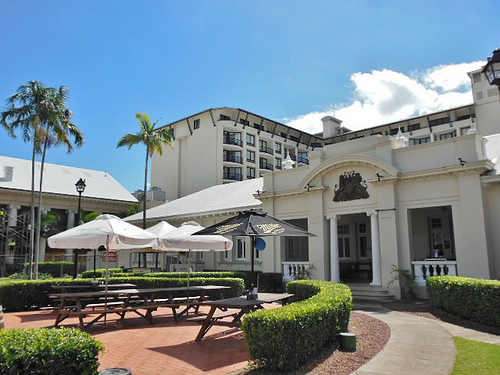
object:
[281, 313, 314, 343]
leaves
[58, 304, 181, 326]
bench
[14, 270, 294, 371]
shade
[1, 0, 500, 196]
sky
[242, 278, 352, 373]
hedge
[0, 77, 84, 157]
palms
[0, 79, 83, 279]
palm tree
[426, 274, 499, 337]
hedge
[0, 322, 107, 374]
hedge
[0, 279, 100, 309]
hedge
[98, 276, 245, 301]
hedge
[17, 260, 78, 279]
hedge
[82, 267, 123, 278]
hedge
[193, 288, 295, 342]
table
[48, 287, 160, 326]
table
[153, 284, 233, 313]
table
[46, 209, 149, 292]
umbrella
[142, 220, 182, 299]
umbrella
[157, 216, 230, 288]
umbrella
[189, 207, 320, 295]
umbrella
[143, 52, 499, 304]
building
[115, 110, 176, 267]
tree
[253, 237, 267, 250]
balloon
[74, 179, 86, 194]
lamp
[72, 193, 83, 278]
post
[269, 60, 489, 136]
cloud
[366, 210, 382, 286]
column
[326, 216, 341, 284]
column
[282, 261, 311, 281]
fence